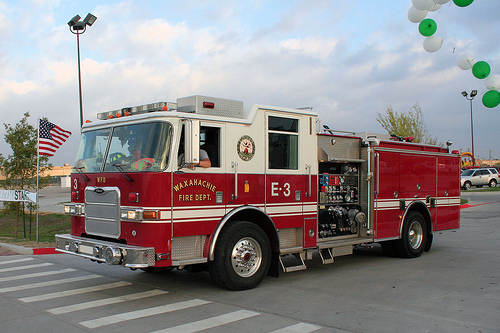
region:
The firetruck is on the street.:
[25, 90, 480, 297]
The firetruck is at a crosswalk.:
[37, 85, 484, 280]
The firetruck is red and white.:
[66, 88, 494, 282]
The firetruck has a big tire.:
[202, 202, 275, 298]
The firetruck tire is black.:
[208, 203, 287, 304]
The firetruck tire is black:
[210, 207, 286, 310]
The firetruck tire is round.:
[214, 213, 299, 302]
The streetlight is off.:
[455, 86, 484, 162]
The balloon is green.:
[478, 88, 498, 110]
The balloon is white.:
[423, 35, 449, 59]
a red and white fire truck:
[67, 89, 467, 281]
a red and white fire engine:
[68, 96, 467, 282]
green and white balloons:
[403, 8, 498, 103]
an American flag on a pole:
[37, 113, 74, 163]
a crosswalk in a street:
[4, 246, 316, 332]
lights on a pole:
[65, 3, 97, 98]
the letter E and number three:
[268, 178, 294, 203]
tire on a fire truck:
[218, 218, 270, 291]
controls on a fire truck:
[317, 161, 364, 235]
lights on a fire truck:
[84, 103, 187, 125]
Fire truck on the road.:
[52, 93, 461, 292]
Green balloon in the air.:
[474, 84, 499, 110]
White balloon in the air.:
[417, 35, 448, 55]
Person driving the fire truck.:
[172, 123, 213, 174]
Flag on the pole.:
[27, 112, 70, 246]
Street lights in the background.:
[457, 84, 479, 157]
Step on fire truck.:
[275, 250, 310, 276]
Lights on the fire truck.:
[90, 96, 177, 121]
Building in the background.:
[0, 157, 72, 181]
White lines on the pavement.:
[1, 252, 323, 332]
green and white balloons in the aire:
[404, 0, 498, 103]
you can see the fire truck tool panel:
[321, 161, 371, 240]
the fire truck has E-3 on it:
[265, 170, 297, 202]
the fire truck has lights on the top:
[78, 93, 180, 120]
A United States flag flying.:
[32, 117, 74, 169]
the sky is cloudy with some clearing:
[86, 3, 421, 80]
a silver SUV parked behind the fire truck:
[461, 165, 498, 198]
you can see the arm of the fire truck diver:
[193, 143, 215, 172]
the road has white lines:
[0, 260, 382, 330]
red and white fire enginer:
[62, 82, 474, 277]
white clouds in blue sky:
[24, 43, 55, 75]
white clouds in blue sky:
[124, 6, 201, 61]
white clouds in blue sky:
[101, 58, 161, 83]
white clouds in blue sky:
[357, 45, 395, 79]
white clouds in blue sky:
[378, 59, 406, 89]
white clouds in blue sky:
[304, 23, 371, 80]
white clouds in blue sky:
[195, 38, 243, 72]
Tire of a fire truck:
[211, 222, 273, 291]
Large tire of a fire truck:
[213, 220, 271, 290]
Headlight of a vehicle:
[122, 208, 140, 224]